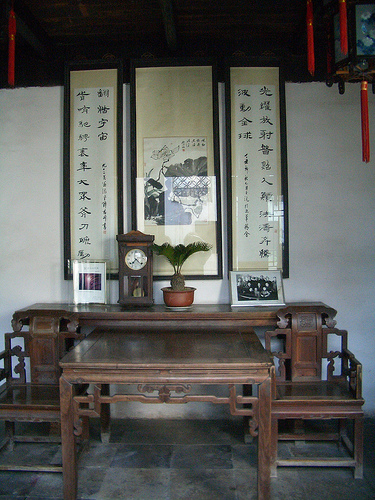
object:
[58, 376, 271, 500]
legs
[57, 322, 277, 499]
table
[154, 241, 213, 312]
plant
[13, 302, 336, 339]
table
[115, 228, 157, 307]
clock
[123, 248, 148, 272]
face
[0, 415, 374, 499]
floor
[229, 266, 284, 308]
photo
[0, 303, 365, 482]
chair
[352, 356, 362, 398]
arms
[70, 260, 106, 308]
picture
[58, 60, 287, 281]
art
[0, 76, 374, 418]
wall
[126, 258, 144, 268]
hands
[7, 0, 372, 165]
tassels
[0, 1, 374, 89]
ceiling